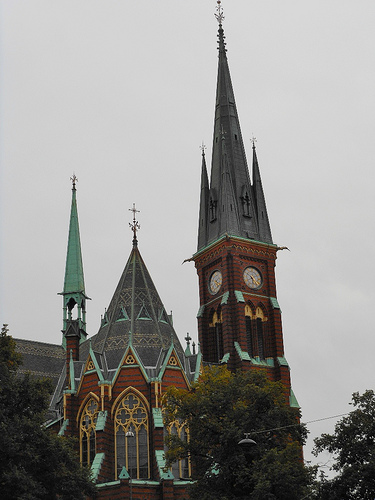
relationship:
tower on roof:
[187, 1, 293, 386] [0, 2, 302, 411]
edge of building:
[94, 478, 166, 488] [3, 2, 312, 499]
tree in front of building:
[2, 321, 99, 497] [3, 2, 312, 499]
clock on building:
[242, 265, 261, 290] [3, 2, 312, 499]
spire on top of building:
[62, 172, 91, 339] [3, 2, 312, 499]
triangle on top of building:
[111, 344, 151, 387] [3, 2, 312, 499]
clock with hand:
[242, 265, 261, 290] [251, 279, 259, 284]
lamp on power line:
[236, 435, 255, 449] [236, 408, 348, 460]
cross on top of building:
[129, 203, 143, 222] [3, 2, 312, 499]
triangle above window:
[111, 344, 151, 387] [111, 385, 152, 477]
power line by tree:
[236, 408, 348, 460] [2, 321, 99, 497]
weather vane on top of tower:
[213, 2, 227, 29] [187, 1, 293, 386]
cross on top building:
[129, 203, 143, 222] [3, 2, 312, 499]